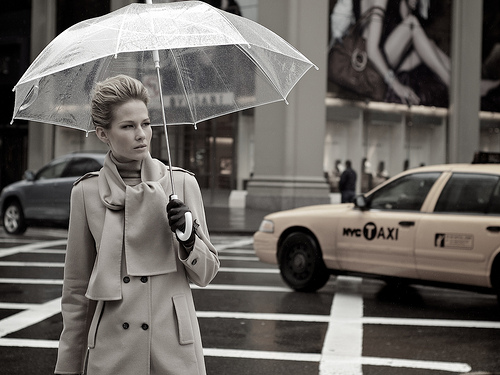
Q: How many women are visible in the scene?
A: One.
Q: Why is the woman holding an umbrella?
A: To protect from the rain.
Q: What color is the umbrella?
A: Transparent.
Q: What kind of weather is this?
A: Rain.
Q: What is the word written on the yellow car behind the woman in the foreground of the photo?
A: NYC Taxi.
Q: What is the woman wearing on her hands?
A: Gloves.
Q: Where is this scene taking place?
A: Crosswalk.